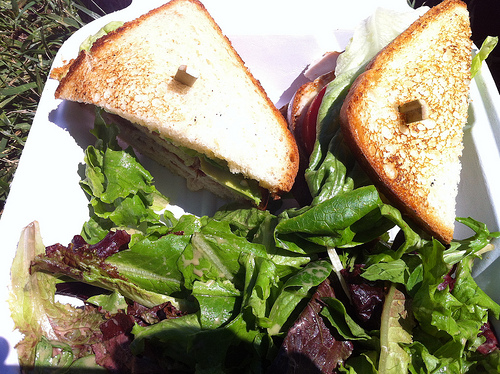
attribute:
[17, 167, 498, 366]
lettuce — green, purple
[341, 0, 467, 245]
bread slices — two slices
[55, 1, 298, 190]
bread slices — two slices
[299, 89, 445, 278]
lettuce — middle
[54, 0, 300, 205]
sandwich — toasted 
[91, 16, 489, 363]
meal — healthy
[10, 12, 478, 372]
dish — white